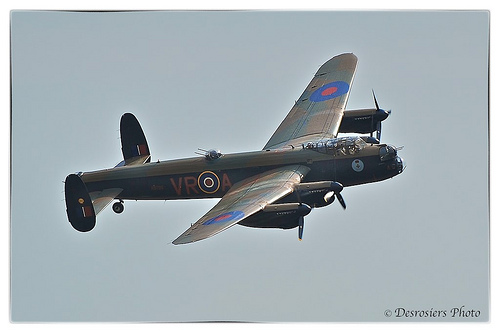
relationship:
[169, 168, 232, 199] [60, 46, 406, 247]
letters on side of plane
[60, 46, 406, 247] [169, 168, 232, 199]
plane has letters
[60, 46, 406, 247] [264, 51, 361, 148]
plane has wing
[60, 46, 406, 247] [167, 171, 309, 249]
plane has wing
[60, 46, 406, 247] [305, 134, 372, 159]
plane has cockpit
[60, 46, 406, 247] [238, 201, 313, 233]
plane has engine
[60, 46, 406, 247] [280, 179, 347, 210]
plane has engine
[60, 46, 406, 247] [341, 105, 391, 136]
plane has engine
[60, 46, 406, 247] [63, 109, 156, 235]
plane has tail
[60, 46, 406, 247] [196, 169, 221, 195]
plane has logo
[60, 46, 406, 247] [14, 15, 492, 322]
plane in sky